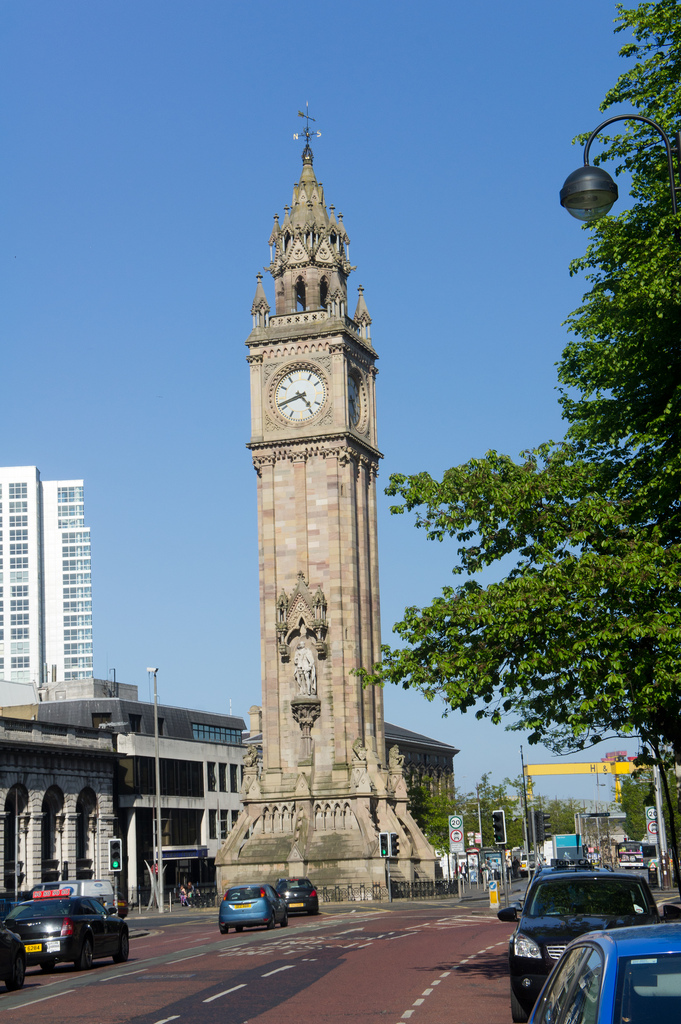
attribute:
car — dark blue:
[271, 868, 323, 915]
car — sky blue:
[525, 918, 679, 1013]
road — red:
[15, 903, 551, 1014]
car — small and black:
[278, 859, 323, 917]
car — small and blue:
[225, 873, 275, 928]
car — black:
[21, 885, 108, 932]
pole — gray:
[452, 848, 469, 875]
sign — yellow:
[495, 746, 644, 775]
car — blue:
[517, 959, 676, 1024]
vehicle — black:
[491, 864, 588, 1002]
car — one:
[21, 889, 132, 973]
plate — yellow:
[17, 936, 50, 963]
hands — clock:
[269, 388, 314, 415]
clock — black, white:
[267, 358, 335, 431]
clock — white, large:
[264, 356, 334, 429]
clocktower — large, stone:
[218, 112, 452, 906]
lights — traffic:
[370, 830, 410, 858]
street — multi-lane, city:
[64, 897, 616, 1008]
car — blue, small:
[219, 886, 287, 931]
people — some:
[172, 879, 207, 907]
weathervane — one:
[265, 97, 339, 156]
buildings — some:
[5, 673, 487, 931]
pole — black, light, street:
[566, 111, 671, 253]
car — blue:
[217, 878, 286, 932]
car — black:
[9, 883, 129, 974]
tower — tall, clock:
[196, 123, 451, 903]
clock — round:
[254, 352, 330, 430]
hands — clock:
[279, 390, 322, 417]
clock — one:
[270, 361, 335, 421]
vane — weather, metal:
[280, 88, 336, 152]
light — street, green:
[109, 835, 123, 875]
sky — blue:
[58, 156, 202, 318]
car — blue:
[515, 912, 671, 1017]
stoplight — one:
[370, 825, 408, 873]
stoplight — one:
[109, 830, 142, 879]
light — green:
[106, 839, 125, 872]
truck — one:
[501, 858, 658, 969]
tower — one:
[220, 219, 455, 892]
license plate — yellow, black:
[19, 942, 47, 953]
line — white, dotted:
[409, 921, 509, 1011]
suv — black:
[495, 867, 651, 1006]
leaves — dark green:
[351, 26, 658, 750]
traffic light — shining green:
[105, 833, 126, 878]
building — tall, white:
[4, 458, 95, 678]